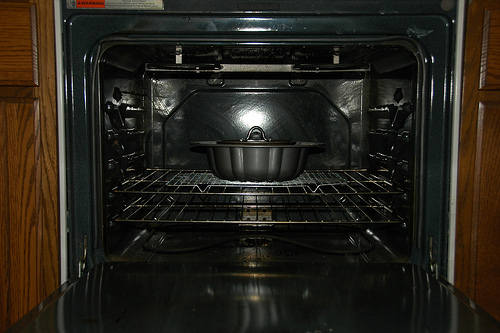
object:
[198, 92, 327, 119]
wall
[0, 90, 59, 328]
door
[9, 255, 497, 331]
door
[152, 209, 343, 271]
burner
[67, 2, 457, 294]
oven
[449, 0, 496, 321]
cabinet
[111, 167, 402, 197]
oven rack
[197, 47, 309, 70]
hook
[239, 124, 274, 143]
handle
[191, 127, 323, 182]
baking pan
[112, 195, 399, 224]
oven rack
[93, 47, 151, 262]
wall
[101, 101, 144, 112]
ridge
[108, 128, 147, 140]
ridge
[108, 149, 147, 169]
ridge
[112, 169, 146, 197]
ridge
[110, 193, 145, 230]
ridge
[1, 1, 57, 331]
cabinet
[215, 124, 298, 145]
lid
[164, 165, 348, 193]
rack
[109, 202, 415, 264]
bottom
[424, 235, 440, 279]
hook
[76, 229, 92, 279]
hook